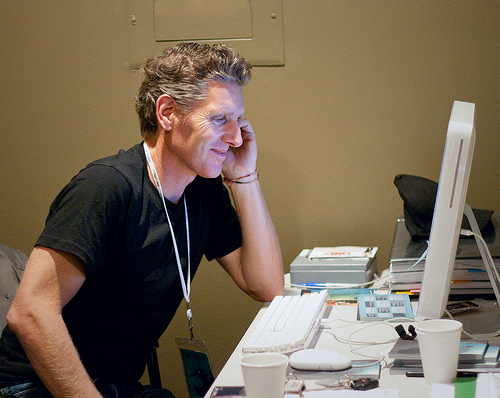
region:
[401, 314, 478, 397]
a white plastic cup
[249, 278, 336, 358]
a white computer keyboard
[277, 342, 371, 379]
a white computer mouse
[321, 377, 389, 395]
a set of keys on a desk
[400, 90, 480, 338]
a white computer monitor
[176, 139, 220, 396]
a man with a tag around his neck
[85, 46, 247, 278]
a man wearing a black shirt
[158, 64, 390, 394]
a man sitting at a desk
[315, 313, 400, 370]
white cords to a computer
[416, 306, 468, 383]
two white plastic cups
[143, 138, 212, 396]
white lanyard hanging on his neck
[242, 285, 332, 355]
white apple computer keyboard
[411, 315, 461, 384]
white paper cups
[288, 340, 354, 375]
white single button mouse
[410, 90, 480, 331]
Apple desktop computer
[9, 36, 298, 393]
man looking at a computer monitor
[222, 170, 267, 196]
bracelet on his left wrist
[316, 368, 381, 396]
keys on the desk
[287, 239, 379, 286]
silver box on the desk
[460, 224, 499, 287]
cable plugged in to the computer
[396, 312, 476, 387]
two plastic cups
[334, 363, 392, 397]
a set of keys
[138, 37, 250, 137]
a man with black and white hair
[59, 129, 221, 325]
a man wearing a black shirt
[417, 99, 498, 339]
an Apple iMac computer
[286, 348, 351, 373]
an Apple Mighty Mouse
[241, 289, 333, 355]
a white Apple USB keyboard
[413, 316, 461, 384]
a white paper cup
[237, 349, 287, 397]
a white paper cup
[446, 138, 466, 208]
a DVD slot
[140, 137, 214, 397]
a white name lanyard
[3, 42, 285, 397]
a man sitting at table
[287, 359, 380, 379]
a computer mouse pad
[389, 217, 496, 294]
a large paper binder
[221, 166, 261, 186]
colorful bracelets on a man's wrist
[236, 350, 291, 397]
white cup on a desk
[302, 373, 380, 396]
keys on a desk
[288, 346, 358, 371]
computer mouse on a pad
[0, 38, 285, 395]
a smiling man sitting on a chair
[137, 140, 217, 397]
tag around a man's neck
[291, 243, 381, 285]
stack of thick books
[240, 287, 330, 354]
white keyboard on a desk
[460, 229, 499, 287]
white plug in a computer monitor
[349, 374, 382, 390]
car key on a desk